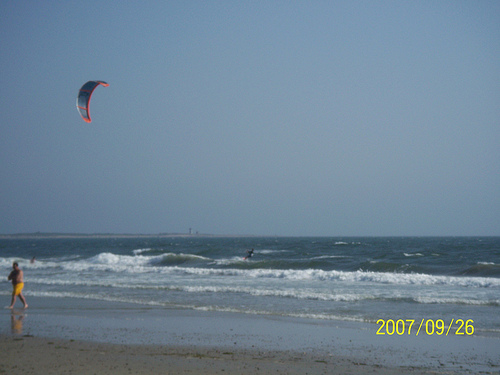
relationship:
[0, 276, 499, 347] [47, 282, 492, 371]
shore water rolling in on sand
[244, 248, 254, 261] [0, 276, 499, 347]
man para sailing in shore water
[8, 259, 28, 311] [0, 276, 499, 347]
man para sailing in shore water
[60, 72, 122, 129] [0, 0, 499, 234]
kite in sky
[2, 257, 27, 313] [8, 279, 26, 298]
man wearing shorts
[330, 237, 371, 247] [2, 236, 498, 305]
wave crashing in ocean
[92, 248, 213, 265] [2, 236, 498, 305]
wave crashing in ocean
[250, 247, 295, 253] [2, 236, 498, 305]
wave crashing in ocean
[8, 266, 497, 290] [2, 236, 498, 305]
wave crashing in ocean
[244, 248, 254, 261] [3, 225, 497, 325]
man in water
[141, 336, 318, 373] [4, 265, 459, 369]
footprints on ground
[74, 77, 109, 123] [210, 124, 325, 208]
kite in sky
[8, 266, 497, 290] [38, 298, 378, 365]
wave crashing into shore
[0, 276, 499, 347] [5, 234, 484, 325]
shore water in ocean